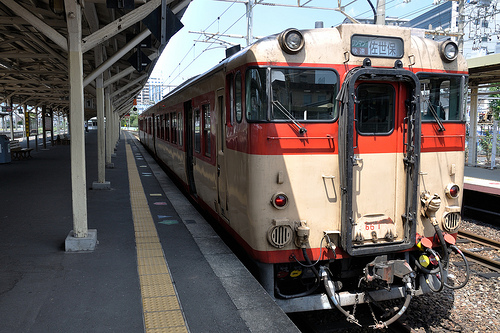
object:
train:
[134, 15, 476, 332]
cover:
[0, 0, 192, 120]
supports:
[57, 1, 99, 255]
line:
[120, 137, 194, 332]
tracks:
[458, 229, 497, 282]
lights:
[278, 24, 311, 58]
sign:
[25, 114, 40, 138]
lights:
[268, 188, 293, 211]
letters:
[368, 38, 380, 56]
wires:
[154, 1, 239, 89]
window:
[353, 70, 400, 137]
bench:
[6, 137, 34, 160]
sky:
[148, 1, 446, 86]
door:
[341, 65, 422, 257]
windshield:
[245, 64, 348, 126]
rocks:
[467, 297, 475, 302]